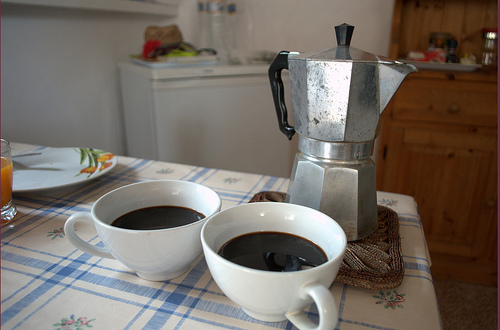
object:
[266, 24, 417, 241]
coffee maker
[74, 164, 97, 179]
flower motif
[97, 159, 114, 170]
flower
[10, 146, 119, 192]
plate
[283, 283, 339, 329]
handle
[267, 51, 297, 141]
handle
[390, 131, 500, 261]
cabinet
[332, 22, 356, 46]
top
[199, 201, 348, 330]
cup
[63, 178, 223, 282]
cup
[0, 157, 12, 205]
juice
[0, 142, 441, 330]
table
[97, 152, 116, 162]
flowers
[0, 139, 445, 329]
table cloth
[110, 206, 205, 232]
coffee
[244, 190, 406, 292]
hotplate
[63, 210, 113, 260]
handle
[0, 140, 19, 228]
drinking glass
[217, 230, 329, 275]
espresso